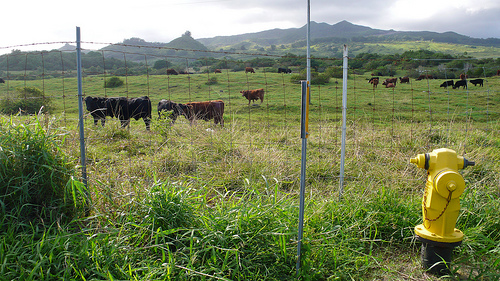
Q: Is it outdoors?
A: Yes, it is outdoors.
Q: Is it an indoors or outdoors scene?
A: It is outdoors.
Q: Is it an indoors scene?
A: No, it is outdoors.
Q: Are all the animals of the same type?
A: Yes, all the animals are cows.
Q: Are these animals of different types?
A: No, all the animals are cows.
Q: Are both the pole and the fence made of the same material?
A: Yes, both the pole and the fence are made of metal.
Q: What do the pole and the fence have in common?
A: The material, both the pole and the fence are metallic.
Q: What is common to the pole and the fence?
A: The material, both the pole and the fence are metallic.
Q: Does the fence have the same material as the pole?
A: Yes, both the fence and the pole are made of metal.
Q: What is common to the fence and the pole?
A: The material, both the fence and the pole are metallic.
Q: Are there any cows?
A: Yes, there are cows.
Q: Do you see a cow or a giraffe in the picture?
A: Yes, there are cows.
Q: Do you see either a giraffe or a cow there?
A: Yes, there are cows.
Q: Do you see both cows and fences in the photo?
A: Yes, there are both cows and a fence.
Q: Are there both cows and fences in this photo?
A: Yes, there are both cows and a fence.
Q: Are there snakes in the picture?
A: No, there are no snakes.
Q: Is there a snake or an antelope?
A: No, there are no snakes or antelopes.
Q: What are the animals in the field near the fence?
A: The animals are cows.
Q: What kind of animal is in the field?
A: The animals are cows.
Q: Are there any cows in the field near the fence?
A: Yes, there are cows in the field.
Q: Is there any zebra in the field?
A: No, there are cows in the field.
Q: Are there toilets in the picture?
A: No, there are no toilets.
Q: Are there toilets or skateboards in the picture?
A: No, there are no toilets or skateboards.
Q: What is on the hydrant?
A: The chain is on the hydrant.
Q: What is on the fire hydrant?
A: The chain is on the hydrant.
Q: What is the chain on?
A: The chain is on the fire hydrant.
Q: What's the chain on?
A: The chain is on the fire hydrant.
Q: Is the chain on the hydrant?
A: Yes, the chain is on the hydrant.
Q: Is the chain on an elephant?
A: No, the chain is on the hydrant.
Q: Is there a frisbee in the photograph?
A: No, there are no frisbees.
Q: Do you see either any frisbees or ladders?
A: No, there are no frisbees or ladders.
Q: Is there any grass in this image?
A: Yes, there is grass.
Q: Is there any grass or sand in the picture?
A: Yes, there is grass.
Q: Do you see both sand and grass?
A: No, there is grass but no sand.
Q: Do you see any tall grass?
A: Yes, there is tall grass.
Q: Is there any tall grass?
A: Yes, there is tall grass.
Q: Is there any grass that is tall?
A: Yes, there is grass that is tall.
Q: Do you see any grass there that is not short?
A: Yes, there is tall grass.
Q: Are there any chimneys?
A: No, there are no chimneys.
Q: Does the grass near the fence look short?
A: No, the grass is tall.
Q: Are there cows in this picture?
A: Yes, there is a cow.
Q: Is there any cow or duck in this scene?
A: Yes, there is a cow.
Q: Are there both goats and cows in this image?
A: No, there is a cow but no goats.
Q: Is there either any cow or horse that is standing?
A: Yes, the cow is standing.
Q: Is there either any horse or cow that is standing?
A: Yes, the cow is standing.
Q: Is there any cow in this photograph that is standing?
A: Yes, there is a cow that is standing.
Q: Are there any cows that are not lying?
A: Yes, there is a cow that is standing.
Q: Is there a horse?
A: No, there are no horses.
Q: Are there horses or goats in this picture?
A: No, there are no horses or goats.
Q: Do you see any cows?
A: Yes, there are cows.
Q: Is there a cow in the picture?
A: Yes, there are cows.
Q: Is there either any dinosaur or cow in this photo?
A: Yes, there are cows.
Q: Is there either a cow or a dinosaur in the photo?
A: Yes, there are cows.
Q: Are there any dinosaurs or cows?
A: Yes, there are cows.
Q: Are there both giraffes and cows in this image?
A: No, there are cows but no giraffes.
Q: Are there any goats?
A: No, there are no goats.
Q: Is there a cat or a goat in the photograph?
A: No, there are no goats or cats.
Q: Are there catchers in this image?
A: No, there are no catchers.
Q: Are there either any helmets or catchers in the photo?
A: No, there are no catchers or helmets.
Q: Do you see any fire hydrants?
A: Yes, there is a fire hydrant.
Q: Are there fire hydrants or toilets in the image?
A: Yes, there is a fire hydrant.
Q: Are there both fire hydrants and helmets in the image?
A: No, there is a fire hydrant but no helmets.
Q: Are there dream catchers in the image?
A: No, there are no dream catchers.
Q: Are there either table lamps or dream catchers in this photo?
A: No, there are no dream catchers or table lamps.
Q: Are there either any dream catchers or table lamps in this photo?
A: No, there are no dream catchers or table lamps.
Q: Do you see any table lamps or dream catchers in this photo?
A: No, there are no dream catchers or table lamps.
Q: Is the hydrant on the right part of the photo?
A: Yes, the hydrant is on the right of the image.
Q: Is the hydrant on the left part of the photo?
A: No, the hydrant is on the right of the image.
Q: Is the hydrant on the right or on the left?
A: The hydrant is on the right of the image.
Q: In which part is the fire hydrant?
A: The fire hydrant is on the right of the image.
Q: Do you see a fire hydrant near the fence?
A: Yes, there is a fire hydrant near the fence.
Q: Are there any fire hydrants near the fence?
A: Yes, there is a fire hydrant near the fence.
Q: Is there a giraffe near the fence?
A: No, there is a fire hydrant near the fence.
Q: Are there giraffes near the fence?
A: No, there is a fire hydrant near the fence.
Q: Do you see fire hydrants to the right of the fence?
A: Yes, there is a fire hydrant to the right of the fence.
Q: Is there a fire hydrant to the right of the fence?
A: Yes, there is a fire hydrant to the right of the fence.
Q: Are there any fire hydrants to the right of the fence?
A: Yes, there is a fire hydrant to the right of the fence.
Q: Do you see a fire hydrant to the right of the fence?
A: Yes, there is a fire hydrant to the right of the fence.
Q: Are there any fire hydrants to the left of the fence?
A: No, the fire hydrant is to the right of the fence.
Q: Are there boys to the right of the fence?
A: No, there is a fire hydrant to the right of the fence.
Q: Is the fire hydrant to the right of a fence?
A: Yes, the fire hydrant is to the right of a fence.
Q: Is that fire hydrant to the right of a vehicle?
A: No, the fire hydrant is to the right of a fence.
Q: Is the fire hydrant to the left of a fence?
A: No, the fire hydrant is to the right of a fence.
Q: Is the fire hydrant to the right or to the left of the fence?
A: The fire hydrant is to the right of the fence.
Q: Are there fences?
A: Yes, there is a fence.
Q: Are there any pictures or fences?
A: Yes, there is a fence.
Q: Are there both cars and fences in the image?
A: No, there is a fence but no cars.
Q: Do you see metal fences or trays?
A: Yes, there is a metal fence.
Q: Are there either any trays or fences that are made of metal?
A: Yes, the fence is made of metal.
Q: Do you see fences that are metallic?
A: Yes, there is a metal fence.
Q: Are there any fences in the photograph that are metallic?
A: Yes, there is a fence that is metallic.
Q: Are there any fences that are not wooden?
A: Yes, there is a metallic fence.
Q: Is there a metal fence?
A: Yes, there is a fence that is made of metal.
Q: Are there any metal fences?
A: Yes, there is a fence that is made of metal.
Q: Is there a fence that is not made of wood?
A: Yes, there is a fence that is made of metal.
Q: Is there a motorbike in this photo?
A: No, there are no motorcycles.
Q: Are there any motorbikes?
A: No, there are no motorbikes.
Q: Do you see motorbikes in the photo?
A: No, there are no motorbikes.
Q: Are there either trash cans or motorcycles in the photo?
A: No, there are no motorcycles or trash cans.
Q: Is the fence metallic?
A: Yes, the fence is metallic.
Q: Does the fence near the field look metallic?
A: Yes, the fence is metallic.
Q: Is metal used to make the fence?
A: Yes, the fence is made of metal.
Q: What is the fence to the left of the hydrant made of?
A: The fence is made of metal.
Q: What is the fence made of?
A: The fence is made of metal.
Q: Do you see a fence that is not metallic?
A: No, there is a fence but it is metallic.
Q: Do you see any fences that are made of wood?
A: No, there is a fence but it is made of metal.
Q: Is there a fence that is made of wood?
A: No, there is a fence but it is made of metal.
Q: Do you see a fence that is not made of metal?
A: No, there is a fence but it is made of metal.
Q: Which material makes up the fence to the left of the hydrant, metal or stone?
A: The fence is made of metal.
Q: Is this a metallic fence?
A: Yes, this is a metallic fence.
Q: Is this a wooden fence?
A: No, this is a metallic fence.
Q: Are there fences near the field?
A: Yes, there is a fence near the field.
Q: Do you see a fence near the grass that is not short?
A: Yes, there is a fence near the grass.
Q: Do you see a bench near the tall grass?
A: No, there is a fence near the grass.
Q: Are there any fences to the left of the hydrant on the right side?
A: Yes, there is a fence to the left of the hydrant.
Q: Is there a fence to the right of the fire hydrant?
A: No, the fence is to the left of the fire hydrant.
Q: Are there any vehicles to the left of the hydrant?
A: No, there is a fence to the left of the hydrant.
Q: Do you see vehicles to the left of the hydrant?
A: No, there is a fence to the left of the hydrant.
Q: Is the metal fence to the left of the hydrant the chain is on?
A: Yes, the fence is to the left of the hydrant.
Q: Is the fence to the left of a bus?
A: No, the fence is to the left of the hydrant.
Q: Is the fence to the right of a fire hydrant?
A: No, the fence is to the left of a fire hydrant.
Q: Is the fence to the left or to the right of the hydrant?
A: The fence is to the left of the hydrant.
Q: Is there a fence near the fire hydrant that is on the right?
A: Yes, there is a fence near the fire hydrant.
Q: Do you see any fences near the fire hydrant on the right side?
A: Yes, there is a fence near the fire hydrant.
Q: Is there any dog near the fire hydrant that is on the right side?
A: No, there is a fence near the fire hydrant.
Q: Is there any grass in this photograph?
A: Yes, there is grass.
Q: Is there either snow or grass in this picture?
A: Yes, there is grass.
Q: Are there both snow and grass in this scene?
A: No, there is grass but no snow.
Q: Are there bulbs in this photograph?
A: No, there are no bulbs.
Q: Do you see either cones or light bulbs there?
A: No, there are no light bulbs or cones.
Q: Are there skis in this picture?
A: No, there are no skis.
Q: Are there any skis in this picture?
A: No, there are no skis.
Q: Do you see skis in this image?
A: No, there are no skis.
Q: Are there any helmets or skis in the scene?
A: No, there are no skis or helmets.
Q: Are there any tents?
A: No, there are no tents.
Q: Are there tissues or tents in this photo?
A: No, there are no tents or tissues.